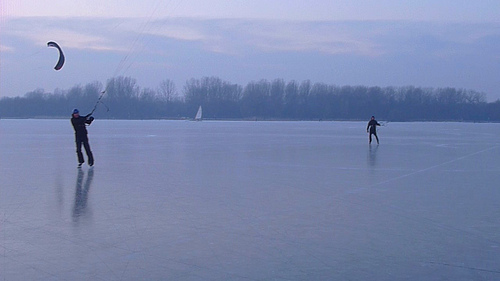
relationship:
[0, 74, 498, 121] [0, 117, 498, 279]
trees surrounding lake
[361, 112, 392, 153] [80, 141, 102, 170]
person on leg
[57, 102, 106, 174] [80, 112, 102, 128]
person has hands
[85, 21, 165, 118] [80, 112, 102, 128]
rope in hands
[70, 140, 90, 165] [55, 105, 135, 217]
leg of person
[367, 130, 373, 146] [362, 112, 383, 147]
leg of person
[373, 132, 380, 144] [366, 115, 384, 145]
leg of person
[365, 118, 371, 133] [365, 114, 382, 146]
arm of person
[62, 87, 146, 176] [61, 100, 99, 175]
arm of person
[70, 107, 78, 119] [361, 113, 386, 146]
head of person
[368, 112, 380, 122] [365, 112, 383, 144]
head of person